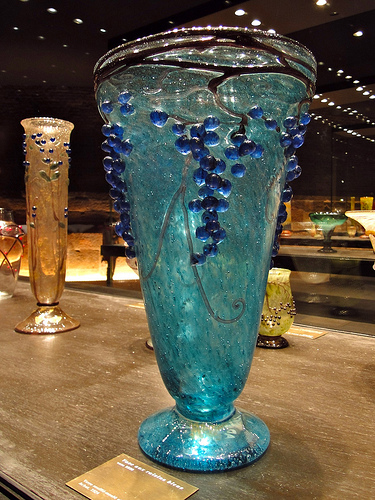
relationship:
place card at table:
[64, 452, 194, 498] [3, 276, 372, 498]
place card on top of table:
[64, 452, 194, 498] [3, 276, 372, 498]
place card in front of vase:
[64, 452, 194, 498] [91, 26, 316, 475]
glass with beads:
[262, 263, 298, 350] [267, 305, 283, 326]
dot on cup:
[189, 253, 205, 269] [92, 27, 316, 471]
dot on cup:
[216, 198, 227, 212] [92, 27, 316, 471]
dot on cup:
[249, 105, 265, 118] [92, 27, 316, 471]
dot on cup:
[149, 109, 168, 127] [92, 27, 316, 471]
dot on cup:
[281, 188, 289, 201] [92, 27, 316, 471]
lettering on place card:
[115, 455, 184, 490] [64, 452, 194, 498]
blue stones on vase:
[92, 89, 308, 269] [12, 116, 83, 337]